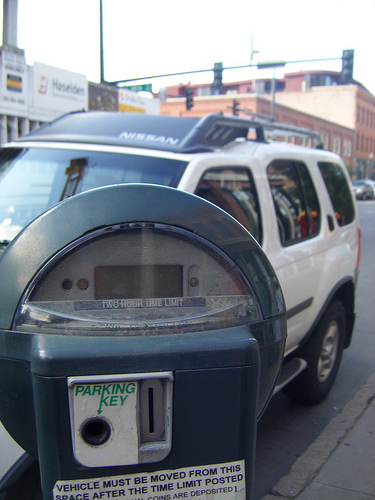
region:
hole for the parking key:
[76, 414, 112, 449]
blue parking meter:
[0, 182, 290, 499]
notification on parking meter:
[47, 460, 248, 499]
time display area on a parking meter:
[13, 224, 262, 329]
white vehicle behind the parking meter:
[0, 109, 364, 410]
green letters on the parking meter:
[75, 383, 136, 414]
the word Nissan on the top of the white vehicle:
[118, 126, 181, 146]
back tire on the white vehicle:
[291, 298, 345, 404]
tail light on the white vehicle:
[355, 228, 361, 270]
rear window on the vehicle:
[317, 155, 357, 228]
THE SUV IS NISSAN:
[112, 115, 178, 156]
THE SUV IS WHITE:
[0, 104, 364, 495]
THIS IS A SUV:
[1, 108, 365, 498]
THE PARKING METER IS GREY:
[0, 179, 290, 497]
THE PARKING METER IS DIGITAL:
[0, 170, 293, 496]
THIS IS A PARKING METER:
[1, 179, 304, 497]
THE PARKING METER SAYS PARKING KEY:
[75, 382, 138, 418]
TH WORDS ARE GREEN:
[70, 378, 136, 423]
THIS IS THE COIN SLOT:
[132, 380, 166, 447]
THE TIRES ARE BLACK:
[291, 275, 356, 413]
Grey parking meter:
[2, 173, 291, 497]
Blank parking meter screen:
[88, 262, 202, 312]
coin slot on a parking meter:
[132, 365, 193, 454]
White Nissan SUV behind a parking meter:
[31, 110, 360, 332]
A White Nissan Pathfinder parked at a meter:
[82, 105, 373, 465]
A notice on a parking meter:
[49, 461, 266, 499]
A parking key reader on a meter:
[55, 375, 143, 470]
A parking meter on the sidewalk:
[9, 172, 292, 496]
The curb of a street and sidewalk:
[292, 381, 372, 494]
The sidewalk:
[334, 406, 373, 498]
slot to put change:
[140, 381, 167, 443]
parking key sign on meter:
[76, 386, 134, 463]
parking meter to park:
[9, 200, 276, 499]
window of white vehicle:
[264, 158, 330, 243]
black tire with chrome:
[298, 296, 354, 407]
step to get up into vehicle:
[282, 354, 312, 392]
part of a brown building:
[304, 89, 373, 144]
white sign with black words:
[53, 455, 258, 498]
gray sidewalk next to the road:
[302, 432, 372, 493]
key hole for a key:
[79, 419, 112, 446]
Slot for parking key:
[76, 415, 116, 449]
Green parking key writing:
[73, 383, 137, 416]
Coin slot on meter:
[140, 382, 165, 438]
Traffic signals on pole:
[206, 43, 362, 99]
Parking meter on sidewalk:
[1, 178, 304, 498]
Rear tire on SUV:
[283, 297, 358, 417]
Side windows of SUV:
[185, 161, 362, 265]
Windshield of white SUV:
[0, 144, 205, 280]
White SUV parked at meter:
[0, 99, 372, 414]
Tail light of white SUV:
[348, 229, 369, 279]